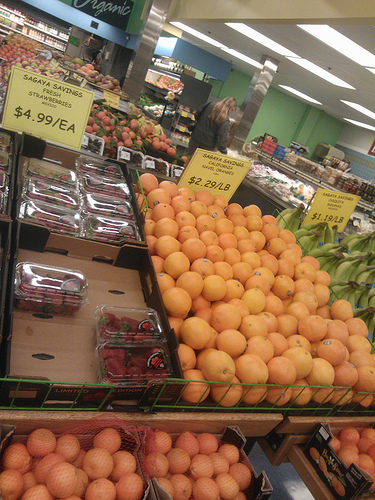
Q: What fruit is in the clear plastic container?
A: Strawberries.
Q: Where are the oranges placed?
A: Rack.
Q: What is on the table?
A: Fruits.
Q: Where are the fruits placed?
A: Container.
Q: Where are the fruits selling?
A: Store.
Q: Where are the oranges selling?
A: Store.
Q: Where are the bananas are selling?
A: Store.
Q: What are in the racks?
A: Fruits.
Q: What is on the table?
A: Oranges.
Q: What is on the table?
A: Oranges.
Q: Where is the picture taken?
A: A supermarket.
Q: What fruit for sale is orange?
A: Oranges.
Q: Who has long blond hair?
A: A woman.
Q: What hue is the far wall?
A: Green.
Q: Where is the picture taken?
A: Store.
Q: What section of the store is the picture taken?
A: Produce.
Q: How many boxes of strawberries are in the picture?
A: 10.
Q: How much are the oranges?
A: $2.29/LB.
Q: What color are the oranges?
A: Orange.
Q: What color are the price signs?
A: Yellow.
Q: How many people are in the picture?
A: One.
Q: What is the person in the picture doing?
A: Shopping.